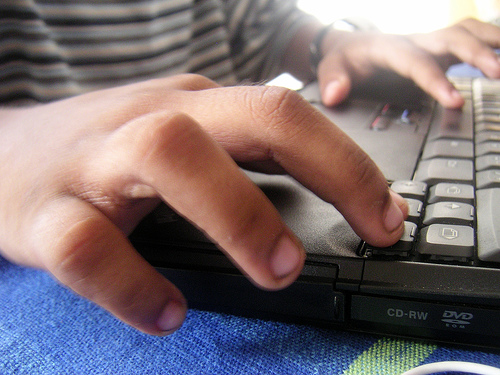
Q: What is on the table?
A: Laptop.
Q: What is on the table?
A: Fingers.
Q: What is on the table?
A: Keyboard.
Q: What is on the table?
A: Keyboard.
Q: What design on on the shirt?
A: Stripes.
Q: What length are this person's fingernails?
A: Short.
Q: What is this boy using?
A: A laptop computer.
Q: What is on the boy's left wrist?
A: A watch.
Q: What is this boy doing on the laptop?
A: Typing.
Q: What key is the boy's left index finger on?
A: Spacebar.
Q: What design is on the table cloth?
A: Strip.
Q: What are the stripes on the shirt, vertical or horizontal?
A: Horizontal.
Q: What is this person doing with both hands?
A: Typing.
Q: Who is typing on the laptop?
A: A boy.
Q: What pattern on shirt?
A: Striped.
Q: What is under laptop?
A: Tablecloth.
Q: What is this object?
A: Keyboard.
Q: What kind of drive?
A: Optical.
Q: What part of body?
A: Hand.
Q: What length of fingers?
A: Short.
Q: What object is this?
A: Keyboard.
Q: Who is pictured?
A: A boy is pictured.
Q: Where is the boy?
A: At his computer.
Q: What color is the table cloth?
A: Blue and green.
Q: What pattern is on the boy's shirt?
A: Stripes.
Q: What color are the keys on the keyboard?
A: Grey.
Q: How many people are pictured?
A: One.